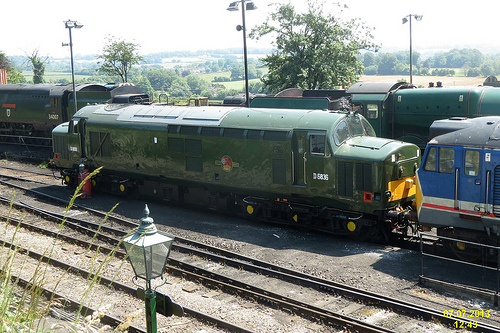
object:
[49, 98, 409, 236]
railroad car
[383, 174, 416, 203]
stripe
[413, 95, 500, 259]
train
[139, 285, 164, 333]
lamppost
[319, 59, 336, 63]
leaves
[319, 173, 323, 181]
numbers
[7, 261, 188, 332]
railroad tracks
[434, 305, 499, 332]
time stamp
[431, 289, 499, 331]
corner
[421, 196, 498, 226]
stripe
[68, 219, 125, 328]
weeds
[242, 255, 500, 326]
tracks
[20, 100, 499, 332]
railroad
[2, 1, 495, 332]
picture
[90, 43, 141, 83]
tree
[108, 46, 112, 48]
leaves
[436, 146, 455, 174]
widow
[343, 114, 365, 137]
windshield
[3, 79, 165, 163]
train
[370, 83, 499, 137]
train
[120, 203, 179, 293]
street lamp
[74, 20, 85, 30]
light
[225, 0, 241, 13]
light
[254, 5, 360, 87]
tree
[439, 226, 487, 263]
wheel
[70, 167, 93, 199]
box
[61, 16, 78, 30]
lamp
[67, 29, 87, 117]
pole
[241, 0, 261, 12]
lamp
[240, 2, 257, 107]
pole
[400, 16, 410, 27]
lamp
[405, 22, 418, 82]
pole